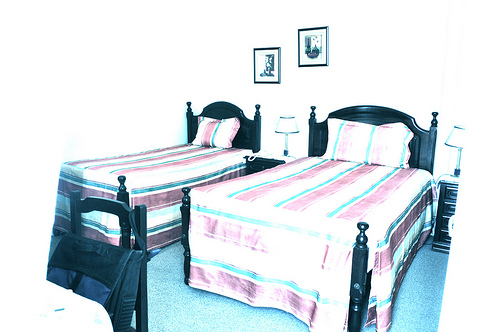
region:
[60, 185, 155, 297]
travel bag set on a chair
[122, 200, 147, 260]
bag's strap looped around the chair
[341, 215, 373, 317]
wooden bed post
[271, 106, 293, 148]
small lamp on a night stand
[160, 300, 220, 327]
blue carpet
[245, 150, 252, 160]
cord of a telephone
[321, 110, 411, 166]
pillow set against a bed's headboard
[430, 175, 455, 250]
wooden night stand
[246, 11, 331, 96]
two pictures framed and hanging on the wall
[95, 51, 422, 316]
two beds set side by side in a room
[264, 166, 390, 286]
the bedspread is striped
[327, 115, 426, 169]
the pillow is striped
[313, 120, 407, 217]
the pillow is on bed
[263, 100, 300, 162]
lamp is on nightstand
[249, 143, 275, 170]
phone is on nightstand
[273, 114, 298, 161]
lam shade is on lamp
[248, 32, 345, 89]
pictures on the wall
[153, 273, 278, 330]
the carpet is brown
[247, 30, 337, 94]
the picture is framed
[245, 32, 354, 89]
two pictures on the wall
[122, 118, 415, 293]
Two twin bed in the room.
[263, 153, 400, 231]
The bedpsread has stripes.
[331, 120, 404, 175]
A pillow on the bed.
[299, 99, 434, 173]
The headboard is black.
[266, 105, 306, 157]
A lamp on the nightstand.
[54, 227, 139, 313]
A bag in the chair.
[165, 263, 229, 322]
The carpet is blue.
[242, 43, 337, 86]
Two pictures on the wall.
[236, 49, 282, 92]
A picture above the bed.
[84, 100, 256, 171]
One bed pushed against the wall.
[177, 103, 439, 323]
a black framed twin bed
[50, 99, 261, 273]
a black framed twin bed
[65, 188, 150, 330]
back of a black chair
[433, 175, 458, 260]
a small black nightstand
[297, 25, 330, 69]
black framed picture on the wall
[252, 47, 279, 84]
black framed picture on the wall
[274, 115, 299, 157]
a small white lamp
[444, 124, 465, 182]
a small white lamp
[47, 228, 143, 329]
a bag on a chair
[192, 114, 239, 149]
pillow on a bed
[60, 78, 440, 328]
Two beds in a bedroom.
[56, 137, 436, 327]
Two striped bedspreads.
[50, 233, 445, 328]
Blue carpet flooring.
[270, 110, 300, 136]
White lampshade with black trim.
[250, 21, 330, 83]
Two pictures on a white wall.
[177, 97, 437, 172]
Two black headboards.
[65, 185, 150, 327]
Part of a wooden chair.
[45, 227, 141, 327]
A black and blue bag on the chair.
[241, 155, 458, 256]
Two wooden nightstands.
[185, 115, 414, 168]
Two striped pillow covers.